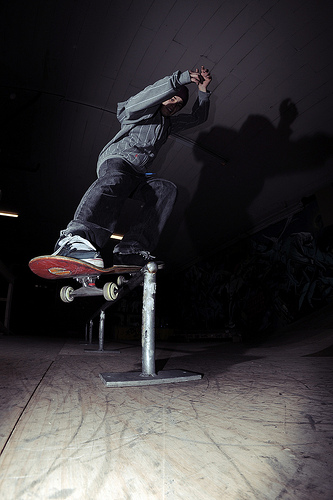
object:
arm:
[117, 66, 190, 121]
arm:
[168, 87, 210, 134]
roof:
[0, 0, 331, 249]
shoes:
[52, 227, 109, 271]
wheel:
[101, 279, 119, 302]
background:
[1, 1, 333, 499]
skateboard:
[27, 252, 166, 303]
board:
[27, 253, 167, 304]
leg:
[140, 264, 161, 380]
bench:
[84, 260, 207, 388]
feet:
[50, 232, 105, 278]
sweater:
[94, 67, 215, 177]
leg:
[61, 156, 137, 245]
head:
[158, 77, 190, 121]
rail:
[85, 259, 159, 376]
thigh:
[141, 176, 174, 192]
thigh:
[98, 148, 130, 182]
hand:
[187, 68, 206, 90]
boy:
[49, 65, 213, 269]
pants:
[56, 157, 179, 256]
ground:
[0, 328, 333, 499]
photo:
[0, 1, 333, 499]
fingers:
[190, 78, 203, 90]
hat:
[173, 84, 193, 108]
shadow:
[185, 98, 331, 283]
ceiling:
[0, 1, 332, 251]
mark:
[191, 421, 260, 498]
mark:
[212, 414, 333, 429]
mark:
[41, 377, 89, 470]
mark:
[112, 401, 136, 468]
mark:
[13, 372, 33, 401]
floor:
[0, 323, 333, 498]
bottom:
[28, 255, 114, 281]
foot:
[49, 232, 105, 267]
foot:
[109, 239, 163, 273]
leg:
[112, 171, 181, 255]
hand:
[197, 65, 214, 94]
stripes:
[123, 88, 174, 112]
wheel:
[59, 284, 75, 304]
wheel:
[115, 273, 128, 293]